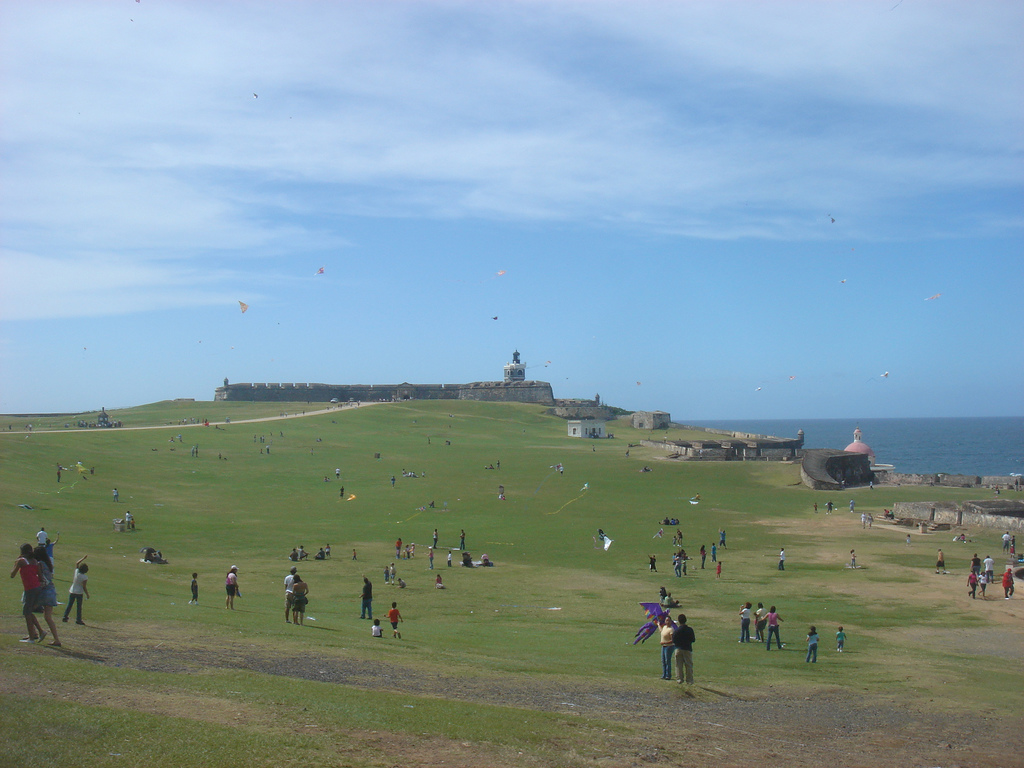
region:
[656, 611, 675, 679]
woman holding purple kite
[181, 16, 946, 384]
a bunch of kites flying in sky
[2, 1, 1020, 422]
light blue cloudy sky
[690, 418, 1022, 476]
dark blue calm seawater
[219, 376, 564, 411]
large rocky wall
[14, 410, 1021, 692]
a bunch of people on a field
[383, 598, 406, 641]
little boy running in a field wearing red shirt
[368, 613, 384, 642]
little kid wearing white shirt sitting in field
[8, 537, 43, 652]
little girl wearing red shirt and dark skirt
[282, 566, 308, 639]
two persons standing in a field holding each other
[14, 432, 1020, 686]
a bunch of people in open field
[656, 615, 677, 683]
person wearing yellow shirt holding purple kite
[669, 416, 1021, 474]
calm dark blue water in the background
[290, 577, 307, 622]
woman standing in field wearing green dress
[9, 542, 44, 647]
little kid wearing red shirt and skirt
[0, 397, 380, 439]
large road to big castle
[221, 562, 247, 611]
woman wearing pink shirt and white cap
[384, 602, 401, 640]
little kid wearing red shirt and shorts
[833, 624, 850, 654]
little blond kid wearing green shirt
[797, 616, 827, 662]
person standing in a field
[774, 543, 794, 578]
person standing in a field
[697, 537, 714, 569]
person standing in a field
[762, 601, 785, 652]
person standing in a field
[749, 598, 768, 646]
person standing in a field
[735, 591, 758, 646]
person standing in a field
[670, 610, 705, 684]
person standing in a field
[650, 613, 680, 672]
person standing in a field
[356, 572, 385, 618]
person standing in a field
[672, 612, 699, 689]
person standing in a field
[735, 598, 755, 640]
person standing in a field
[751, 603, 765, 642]
person standing in a field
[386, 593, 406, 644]
person standing in a field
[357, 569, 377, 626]
person standing in a field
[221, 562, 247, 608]
person standing in a field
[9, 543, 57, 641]
person standing in a field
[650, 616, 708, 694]
a person in the field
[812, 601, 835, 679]
a person in the field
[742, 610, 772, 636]
a person in the field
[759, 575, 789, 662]
a person in the field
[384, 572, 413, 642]
a person in the field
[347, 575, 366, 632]
a person in the field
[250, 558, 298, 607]
a person in the field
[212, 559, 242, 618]
a person in the field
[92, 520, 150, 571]
a person in the field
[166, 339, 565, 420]
large gray castle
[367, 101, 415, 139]
white clouds and kites in blue sky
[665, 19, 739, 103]
white clouds and kites in blue sky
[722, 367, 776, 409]
white clouds and kites in blue sky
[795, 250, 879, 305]
white clouds and kites in blue sky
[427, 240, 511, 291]
white clouds and kites in blue sky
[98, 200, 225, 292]
white clouds and kites in blue sky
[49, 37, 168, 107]
kites and white clouds in blue sky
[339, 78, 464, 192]
kites and white clouds in blue sky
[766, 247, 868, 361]
kites and white clouds in blue sky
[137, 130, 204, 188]
kites and white clouds in blue sky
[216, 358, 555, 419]
large building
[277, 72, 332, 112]
kites and white clouds in blue sky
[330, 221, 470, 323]
kites and white clouds in blue sky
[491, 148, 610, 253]
kites and white clouds in blue sky